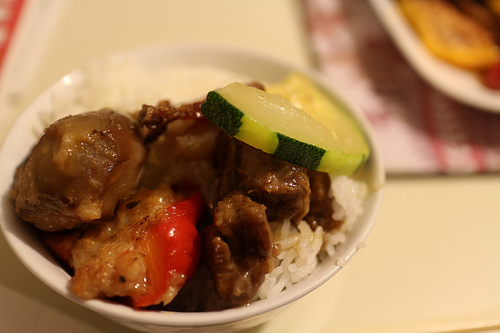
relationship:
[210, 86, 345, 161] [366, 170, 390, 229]
cucumber on plate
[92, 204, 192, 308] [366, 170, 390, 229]
chicken in plate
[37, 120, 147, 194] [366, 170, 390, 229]
beef in plate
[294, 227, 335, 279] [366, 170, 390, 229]
rice in plate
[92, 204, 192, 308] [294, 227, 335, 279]
chicken near rice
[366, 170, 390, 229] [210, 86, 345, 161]
plate holds cucumber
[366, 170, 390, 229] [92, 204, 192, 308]
plate holds chicken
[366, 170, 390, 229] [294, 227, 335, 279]
plate holds rice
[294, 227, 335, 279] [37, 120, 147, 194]
rice near beef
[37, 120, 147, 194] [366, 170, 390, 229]
beef on plate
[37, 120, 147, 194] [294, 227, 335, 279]
beef near rice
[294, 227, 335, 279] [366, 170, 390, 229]
rice on plate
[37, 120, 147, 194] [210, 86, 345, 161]
beef near cucumber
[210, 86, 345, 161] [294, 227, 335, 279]
cucumber near rice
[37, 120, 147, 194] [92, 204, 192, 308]
beef near chicken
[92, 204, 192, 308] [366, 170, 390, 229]
chicken on plate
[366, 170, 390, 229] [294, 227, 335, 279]
plate has rice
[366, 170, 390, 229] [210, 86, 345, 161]
plate has cucumber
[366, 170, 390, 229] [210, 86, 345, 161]
plate holding cucumber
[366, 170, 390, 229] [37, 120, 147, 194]
plate holding beef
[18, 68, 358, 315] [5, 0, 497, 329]
meal on table